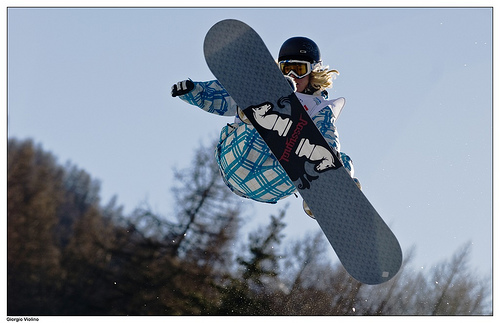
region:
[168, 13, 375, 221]
this is a person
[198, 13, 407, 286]
this is a skating board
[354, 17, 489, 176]
this is the sky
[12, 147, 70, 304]
this is arid vegetation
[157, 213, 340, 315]
this is a arid vegetation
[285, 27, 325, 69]
girl has black helmet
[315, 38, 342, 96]
girl has blonde hair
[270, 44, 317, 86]
white and orange goggles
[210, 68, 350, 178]
blue and white coat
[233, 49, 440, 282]
grey and blue board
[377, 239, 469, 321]
tall and bare trees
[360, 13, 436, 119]
no clouds in sky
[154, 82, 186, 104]
black and white gloves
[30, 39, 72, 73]
white clouds n blue sky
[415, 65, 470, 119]
white clouds n blue sky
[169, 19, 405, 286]
A woman riding a snowboard.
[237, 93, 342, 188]
A logo on a snow board.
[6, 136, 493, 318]
A field of trees.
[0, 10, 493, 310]
A clear blue sky.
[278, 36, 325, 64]
A helmet on a woman's head.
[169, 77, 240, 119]
the right arm of a woman.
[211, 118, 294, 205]
A pair of plaid pants.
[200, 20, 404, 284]
A blue snow board.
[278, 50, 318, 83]
A pair of white goggles.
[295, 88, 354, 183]
The left side of a woman.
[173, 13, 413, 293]
man on black snow board in ait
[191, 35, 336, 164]
man wearing ugly clothes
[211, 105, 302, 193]
man wearing wbhite shorts with blue plaid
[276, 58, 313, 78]
man wearing orange goggles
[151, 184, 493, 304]
row of evergreen trees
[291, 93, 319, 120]
boy flipping in air on surfboard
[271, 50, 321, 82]
orange goggles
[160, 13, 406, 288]
this is a person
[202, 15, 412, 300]
this is a skating board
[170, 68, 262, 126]
this is a person,s hand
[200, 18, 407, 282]
snowboard is in the air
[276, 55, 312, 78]
snow glasses are on person face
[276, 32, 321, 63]
helmet is black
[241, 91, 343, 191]
sticker is on the back of snowboard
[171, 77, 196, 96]
glove is on person hand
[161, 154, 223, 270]
evergreen tree behind the snow boarder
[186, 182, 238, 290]
evergreen tree behind the snow boarder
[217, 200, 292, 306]
evergreen tree behind the snow boarder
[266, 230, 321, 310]
evergreen tree behind the snow boarder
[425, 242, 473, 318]
evergreen tree behind the snow boarder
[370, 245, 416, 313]
evergreen tree behind the snow boarder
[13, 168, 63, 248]
evergreen tree behind the snow boarder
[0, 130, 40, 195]
evergreen tree behind the snow boarder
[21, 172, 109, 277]
evergreen tree behind the snow boarder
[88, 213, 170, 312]
evergreen tree behind the snow boarder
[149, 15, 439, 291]
a snowboarder in the air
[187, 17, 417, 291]
a snowboard in the air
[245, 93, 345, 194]
a pattern on a snowboard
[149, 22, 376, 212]
man wearing snowboarding clothes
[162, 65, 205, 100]
black and white glove on a hand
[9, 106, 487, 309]
rows of trees on a hill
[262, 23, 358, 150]
person with long hair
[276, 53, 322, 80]
white and blue snow goggles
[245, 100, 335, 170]
chess pieces decorate the bottom of a snowboard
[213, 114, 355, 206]
blue and white checkered snowboarding pants